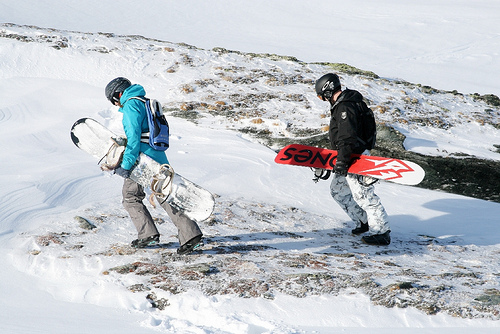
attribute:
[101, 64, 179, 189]
ski jacket — blue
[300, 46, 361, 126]
helmet — black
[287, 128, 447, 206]
snowboard — red, white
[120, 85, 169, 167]
jacket — blue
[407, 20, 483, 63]
clouds — white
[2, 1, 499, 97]
sky — blue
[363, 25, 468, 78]
clouds — white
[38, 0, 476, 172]
sky — blue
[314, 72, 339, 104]
head — of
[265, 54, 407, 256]
person — with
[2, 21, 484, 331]
snow — white